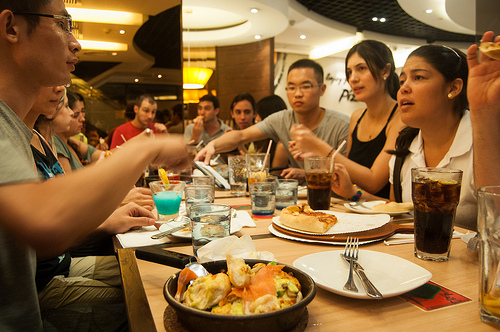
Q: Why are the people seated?
A: To eat.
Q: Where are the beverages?
A: Table.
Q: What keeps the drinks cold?
A: Ice.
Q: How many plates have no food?
A: One.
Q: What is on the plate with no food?
A: Utensils.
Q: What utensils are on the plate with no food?
A: Fork and knife.